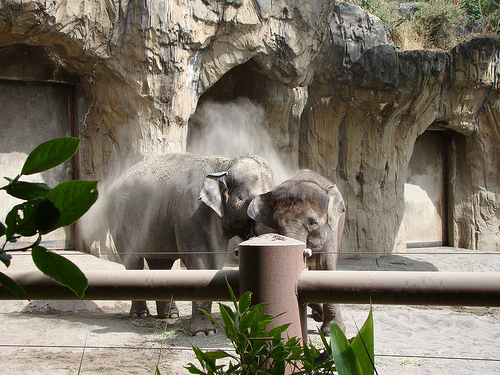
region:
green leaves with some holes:
[5, 125, 110, 241]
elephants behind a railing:
[88, 133, 380, 355]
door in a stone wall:
[353, 80, 499, 247]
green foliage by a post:
[185, 226, 390, 373]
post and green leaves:
[189, 223, 364, 373]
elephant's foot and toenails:
[182, 315, 223, 343]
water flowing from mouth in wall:
[179, 40, 311, 162]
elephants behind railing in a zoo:
[73, 52, 477, 357]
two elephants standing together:
[63, 122, 364, 271]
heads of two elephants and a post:
[200, 145, 357, 367]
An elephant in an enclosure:
[248, 167, 345, 339]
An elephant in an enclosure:
[103, 145, 275, 335]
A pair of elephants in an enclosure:
[98, 132, 342, 325]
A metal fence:
[3, 234, 499, 374]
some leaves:
[3, 134, 98, 313]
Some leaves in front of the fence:
[183, 279, 378, 374]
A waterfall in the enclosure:
[196, 92, 286, 172]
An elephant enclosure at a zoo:
[3, 3, 495, 373]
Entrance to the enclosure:
[406, 127, 449, 246]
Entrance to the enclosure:
[2, 77, 77, 245]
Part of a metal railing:
[304, 265, 497, 312]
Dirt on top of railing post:
[251, 229, 296, 249]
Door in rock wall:
[409, 111, 460, 258]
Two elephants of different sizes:
[101, 151, 354, 277]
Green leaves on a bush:
[216, 281, 324, 374]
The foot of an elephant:
[159, 303, 185, 322]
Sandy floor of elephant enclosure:
[383, 309, 490, 350]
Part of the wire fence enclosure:
[59, 321, 186, 373]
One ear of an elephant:
[191, 168, 235, 218]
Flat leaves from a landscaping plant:
[328, 320, 372, 372]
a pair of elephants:
[91, 145, 420, 331]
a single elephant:
[86, 145, 275, 339]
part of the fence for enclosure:
[22, 232, 493, 321]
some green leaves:
[8, 125, 103, 319]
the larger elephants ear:
[194, 164, 234, 226]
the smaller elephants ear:
[320, 181, 351, 236]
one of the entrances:
[408, 120, 474, 257]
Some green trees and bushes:
[371, 0, 495, 55]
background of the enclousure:
[0, 40, 497, 154]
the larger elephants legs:
[121, 244, 229, 336]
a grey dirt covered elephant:
[101, 154, 275, 336]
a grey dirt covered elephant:
[247, 167, 348, 338]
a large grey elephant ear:
[199, 167, 230, 215]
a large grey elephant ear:
[246, 190, 276, 231]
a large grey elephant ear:
[323, 181, 347, 231]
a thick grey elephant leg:
[182, 243, 223, 336]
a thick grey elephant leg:
[122, 241, 151, 316]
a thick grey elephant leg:
[145, 248, 178, 320]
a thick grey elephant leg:
[318, 246, 346, 334]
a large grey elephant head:
[268, 178, 330, 250]